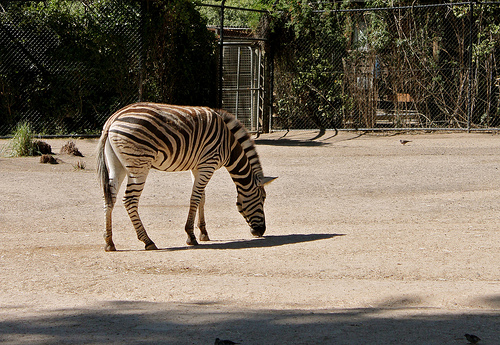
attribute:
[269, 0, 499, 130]
fence — chain link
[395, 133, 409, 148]
bird — small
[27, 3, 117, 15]
bush — green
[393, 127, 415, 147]
bird — small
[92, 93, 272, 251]
zebra — striped